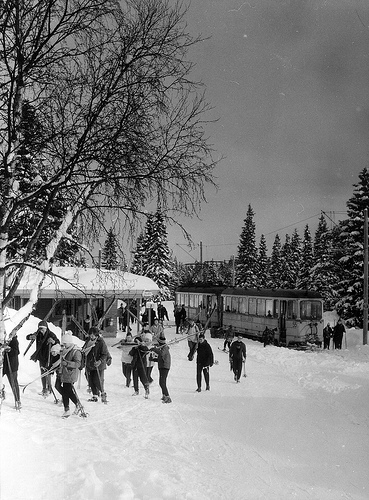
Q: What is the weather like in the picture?
A: It is clear.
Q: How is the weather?
A: It is clear.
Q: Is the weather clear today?
A: Yes, it is clear.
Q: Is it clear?
A: Yes, it is clear.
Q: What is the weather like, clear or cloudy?
A: It is clear.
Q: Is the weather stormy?
A: No, it is clear.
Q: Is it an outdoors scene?
A: Yes, it is outdoors.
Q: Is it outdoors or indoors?
A: It is outdoors.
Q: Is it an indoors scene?
A: No, it is outdoors.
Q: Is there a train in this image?
A: Yes, there is a train.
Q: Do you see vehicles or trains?
A: Yes, there is a train.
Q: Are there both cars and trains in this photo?
A: No, there is a train but no cars.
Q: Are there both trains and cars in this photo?
A: No, there is a train but no cars.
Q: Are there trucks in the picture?
A: No, there are no trucks.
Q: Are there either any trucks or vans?
A: No, there are no trucks or vans.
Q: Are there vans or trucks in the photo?
A: No, there are no trucks or vans.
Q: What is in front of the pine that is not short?
A: The train is in front of the pine tree.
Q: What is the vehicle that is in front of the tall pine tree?
A: The vehicle is a train.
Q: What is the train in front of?
A: The train is in front of the pine tree.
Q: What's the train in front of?
A: The train is in front of the pine tree.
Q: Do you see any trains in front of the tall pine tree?
A: Yes, there is a train in front of the pine tree.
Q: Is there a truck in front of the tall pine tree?
A: No, there is a train in front of the pine tree.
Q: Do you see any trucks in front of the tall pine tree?
A: No, there is a train in front of the pine tree.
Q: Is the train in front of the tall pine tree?
A: Yes, the train is in front of the pine tree.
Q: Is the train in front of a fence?
A: No, the train is in front of the pine tree.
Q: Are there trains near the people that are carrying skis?
A: Yes, there is a train near the people.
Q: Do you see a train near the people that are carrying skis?
A: Yes, there is a train near the people.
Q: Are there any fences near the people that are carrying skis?
A: No, there is a train near the people.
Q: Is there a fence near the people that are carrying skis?
A: No, there is a train near the people.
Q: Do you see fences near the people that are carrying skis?
A: No, there is a train near the people.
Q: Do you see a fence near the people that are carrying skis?
A: No, there is a train near the people.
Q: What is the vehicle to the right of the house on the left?
A: The vehicle is a train.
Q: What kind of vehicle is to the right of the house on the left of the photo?
A: The vehicle is a train.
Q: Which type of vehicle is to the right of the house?
A: The vehicle is a train.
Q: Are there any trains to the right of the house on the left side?
A: Yes, there is a train to the right of the house.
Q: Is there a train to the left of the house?
A: No, the train is to the right of the house.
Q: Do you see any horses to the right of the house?
A: No, there is a train to the right of the house.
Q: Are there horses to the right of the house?
A: No, there is a train to the right of the house.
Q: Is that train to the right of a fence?
A: No, the train is to the right of the house.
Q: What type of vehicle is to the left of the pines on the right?
A: The vehicle is a train.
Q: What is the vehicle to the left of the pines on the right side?
A: The vehicle is a train.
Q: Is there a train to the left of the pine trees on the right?
A: Yes, there is a train to the left of the pines.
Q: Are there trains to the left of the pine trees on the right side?
A: Yes, there is a train to the left of the pines.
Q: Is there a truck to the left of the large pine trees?
A: No, there is a train to the left of the pines.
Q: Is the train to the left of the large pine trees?
A: Yes, the train is to the left of the pine trees.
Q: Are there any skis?
A: Yes, there are skis.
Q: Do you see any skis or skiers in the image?
A: Yes, there are skis.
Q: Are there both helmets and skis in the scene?
A: No, there are skis but no helmets.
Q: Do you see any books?
A: No, there are no books.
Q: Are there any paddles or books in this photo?
A: No, there are no books or paddles.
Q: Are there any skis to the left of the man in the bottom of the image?
A: Yes, there are skis to the left of the man.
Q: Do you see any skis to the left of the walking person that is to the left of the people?
A: Yes, there are skis to the left of the man.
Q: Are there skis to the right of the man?
A: No, the skis are to the left of the man.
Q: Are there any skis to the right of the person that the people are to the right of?
A: No, the skis are to the left of the man.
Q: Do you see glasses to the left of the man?
A: No, there are skis to the left of the man.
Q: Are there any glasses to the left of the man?
A: No, there are skis to the left of the man.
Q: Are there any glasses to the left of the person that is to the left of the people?
A: No, there are skis to the left of the man.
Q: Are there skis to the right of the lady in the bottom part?
A: Yes, there are skis to the right of the lady.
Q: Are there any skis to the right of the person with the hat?
A: Yes, there are skis to the right of the lady.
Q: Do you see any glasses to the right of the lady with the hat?
A: No, there are skis to the right of the lady.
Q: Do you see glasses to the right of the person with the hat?
A: No, there are skis to the right of the lady.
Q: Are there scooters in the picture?
A: No, there are no scooters.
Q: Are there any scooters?
A: No, there are no scooters.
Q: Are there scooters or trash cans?
A: No, there are no scooters or trash cans.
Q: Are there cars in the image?
A: No, there are no cars.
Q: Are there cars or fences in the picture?
A: No, there are no cars or fences.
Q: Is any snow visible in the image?
A: Yes, there is snow.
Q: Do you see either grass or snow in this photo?
A: Yes, there is snow.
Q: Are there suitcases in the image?
A: No, there are no suitcases.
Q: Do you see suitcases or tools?
A: No, there are no suitcases or tools.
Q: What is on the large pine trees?
A: The snow is on the pines.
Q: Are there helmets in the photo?
A: No, there are no helmets.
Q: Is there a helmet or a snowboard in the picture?
A: No, there are no helmets or snowboards.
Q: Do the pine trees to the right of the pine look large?
A: Yes, the pines are large.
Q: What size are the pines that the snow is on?
A: The pines are large.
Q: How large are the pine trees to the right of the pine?
A: The pines are large.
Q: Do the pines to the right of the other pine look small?
A: No, the pine trees are large.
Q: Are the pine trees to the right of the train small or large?
A: The pines are large.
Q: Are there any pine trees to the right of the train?
A: Yes, there are pine trees to the right of the train.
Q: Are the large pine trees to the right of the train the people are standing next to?
A: Yes, the pine trees are to the right of the train.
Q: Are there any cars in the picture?
A: No, there are no cars.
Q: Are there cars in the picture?
A: No, there are no cars.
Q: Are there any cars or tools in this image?
A: No, there are no cars or tools.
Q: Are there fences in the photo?
A: No, there are no fences.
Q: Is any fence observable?
A: No, there are no fences.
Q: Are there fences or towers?
A: No, there are no fences or towers.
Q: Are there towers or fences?
A: No, there are no fences or towers.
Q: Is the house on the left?
A: Yes, the house is on the left of the image.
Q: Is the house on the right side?
A: No, the house is on the left of the image.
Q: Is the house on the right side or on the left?
A: The house is on the left of the image.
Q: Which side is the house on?
A: The house is on the left of the image.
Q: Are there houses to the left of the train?
A: Yes, there is a house to the left of the train.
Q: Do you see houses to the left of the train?
A: Yes, there is a house to the left of the train.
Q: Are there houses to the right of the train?
A: No, the house is to the left of the train.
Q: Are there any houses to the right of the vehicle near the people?
A: No, the house is to the left of the train.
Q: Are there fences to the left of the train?
A: No, there is a house to the left of the train.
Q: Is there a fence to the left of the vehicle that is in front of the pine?
A: No, there is a house to the left of the train.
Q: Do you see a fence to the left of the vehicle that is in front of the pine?
A: No, there is a house to the left of the train.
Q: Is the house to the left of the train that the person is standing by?
A: Yes, the house is to the left of the train.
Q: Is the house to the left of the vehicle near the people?
A: Yes, the house is to the left of the train.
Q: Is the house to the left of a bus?
A: No, the house is to the left of the train.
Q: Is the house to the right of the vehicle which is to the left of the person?
A: No, the house is to the left of the train.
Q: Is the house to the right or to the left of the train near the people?
A: The house is to the left of the train.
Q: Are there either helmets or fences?
A: No, there are no fences or helmets.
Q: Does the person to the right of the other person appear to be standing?
A: Yes, the person is standing.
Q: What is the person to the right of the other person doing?
A: The person is standing.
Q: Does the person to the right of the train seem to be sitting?
A: No, the person is standing.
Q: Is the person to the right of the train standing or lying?
A: The person is standing.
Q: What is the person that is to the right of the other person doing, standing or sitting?
A: The person is standing.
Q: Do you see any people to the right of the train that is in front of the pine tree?
A: Yes, there is a person to the right of the train.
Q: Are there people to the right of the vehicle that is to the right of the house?
A: Yes, there is a person to the right of the train.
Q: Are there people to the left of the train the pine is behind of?
A: No, the person is to the right of the train.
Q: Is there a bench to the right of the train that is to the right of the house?
A: No, there is a person to the right of the train.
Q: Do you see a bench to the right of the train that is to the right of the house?
A: No, there is a person to the right of the train.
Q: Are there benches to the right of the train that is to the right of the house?
A: No, there is a person to the right of the train.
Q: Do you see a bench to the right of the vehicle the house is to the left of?
A: No, there is a person to the right of the train.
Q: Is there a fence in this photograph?
A: No, there are no fences.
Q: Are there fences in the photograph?
A: No, there are no fences.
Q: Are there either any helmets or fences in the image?
A: No, there are no fences or helmets.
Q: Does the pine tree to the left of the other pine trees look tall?
A: Yes, the pine tree is tall.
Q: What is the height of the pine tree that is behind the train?
A: The pine tree is tall.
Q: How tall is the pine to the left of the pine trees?
A: The pine is tall.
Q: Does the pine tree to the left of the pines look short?
A: No, the pine is tall.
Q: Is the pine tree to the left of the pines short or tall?
A: The pine is tall.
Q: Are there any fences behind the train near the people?
A: No, there is a pine tree behind the train.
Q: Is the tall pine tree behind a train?
A: Yes, the pine is behind a train.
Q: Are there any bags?
A: No, there are no bags.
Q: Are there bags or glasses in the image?
A: No, there are no bags or glasses.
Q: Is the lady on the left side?
A: Yes, the lady is on the left of the image.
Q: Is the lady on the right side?
A: No, the lady is on the left of the image.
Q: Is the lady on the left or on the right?
A: The lady is on the left of the image.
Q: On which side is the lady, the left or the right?
A: The lady is on the left of the image.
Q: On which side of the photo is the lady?
A: The lady is on the left of the image.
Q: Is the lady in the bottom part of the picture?
A: Yes, the lady is in the bottom of the image.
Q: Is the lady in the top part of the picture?
A: No, the lady is in the bottom of the image.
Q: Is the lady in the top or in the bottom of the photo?
A: The lady is in the bottom of the image.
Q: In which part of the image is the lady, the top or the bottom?
A: The lady is in the bottom of the image.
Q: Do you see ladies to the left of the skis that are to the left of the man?
A: Yes, there is a lady to the left of the skis.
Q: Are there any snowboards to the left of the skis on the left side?
A: No, there is a lady to the left of the skis.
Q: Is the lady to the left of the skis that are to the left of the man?
A: Yes, the lady is to the left of the skis.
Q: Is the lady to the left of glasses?
A: No, the lady is to the left of the skis.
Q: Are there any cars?
A: No, there are no cars.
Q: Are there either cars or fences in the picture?
A: No, there are no cars or fences.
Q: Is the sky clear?
A: Yes, the sky is clear.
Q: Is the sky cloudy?
A: No, the sky is clear.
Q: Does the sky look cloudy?
A: No, the sky is clear.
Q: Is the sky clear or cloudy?
A: The sky is clear.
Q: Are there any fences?
A: No, there are no fences.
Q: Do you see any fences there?
A: No, there are no fences.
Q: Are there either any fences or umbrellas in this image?
A: No, there are no fences or umbrellas.